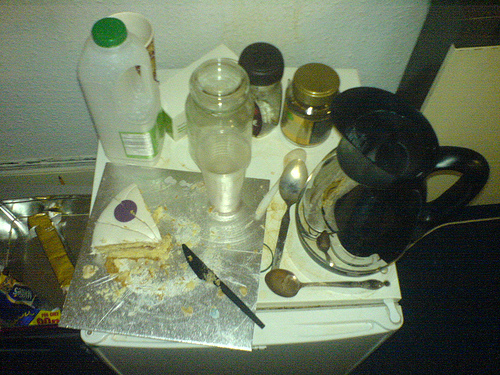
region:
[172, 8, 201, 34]
this is the wall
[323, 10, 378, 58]
the wall is white in color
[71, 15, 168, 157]
this is a bottle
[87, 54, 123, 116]
the bottle is made of plastic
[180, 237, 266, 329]
this is a knife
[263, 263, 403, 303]
this is a spoon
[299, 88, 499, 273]
this is a kettle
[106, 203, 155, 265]
this is a piece of cake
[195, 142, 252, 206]
these are some cups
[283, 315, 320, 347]
the fridge is white in color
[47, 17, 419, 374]
bottles in top of a fridge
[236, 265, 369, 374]
the fridge is white in colour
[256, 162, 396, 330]
spoons are on top of the fridge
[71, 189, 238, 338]
leftovers of a cake on thop of the fridge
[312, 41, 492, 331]
the jug is black in colour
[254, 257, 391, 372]
the fridge is closed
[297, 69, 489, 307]
the jug is shiny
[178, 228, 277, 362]
a knife is on top of the chopping board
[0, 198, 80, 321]
the sink is silver in colour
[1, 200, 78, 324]
paper packs inside the fridge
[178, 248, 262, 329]
this is a knife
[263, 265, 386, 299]
this is a spoon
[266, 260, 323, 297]
the spoon is metallic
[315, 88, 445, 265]
this is a kettle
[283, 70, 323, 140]
this is a container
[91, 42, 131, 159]
this is a bottle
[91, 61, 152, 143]
the bottle is made of plastic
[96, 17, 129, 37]
this is the lid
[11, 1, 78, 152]
this is the wall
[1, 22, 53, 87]
the wall is white in color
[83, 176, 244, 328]
leftover eaten white cake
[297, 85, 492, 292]
silver jug with handle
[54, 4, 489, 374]
serving area on top of mini fridge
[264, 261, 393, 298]
dirty silver spoon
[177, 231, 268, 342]
used black plastic knife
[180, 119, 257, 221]
clear plastic empty cups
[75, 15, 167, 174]
empty plastic container with green top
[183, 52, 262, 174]
clear empty glass jar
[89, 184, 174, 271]
pieces of cake with white frosting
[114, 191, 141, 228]
purple circle decoration on top of cake piece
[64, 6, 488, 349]
items on top of refrigerator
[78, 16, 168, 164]
green cap on jug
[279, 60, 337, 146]
jar with gold lid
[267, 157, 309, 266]
silver spoon with glare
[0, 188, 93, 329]
stainless steel kitchen sink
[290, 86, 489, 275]
coffee server with black handle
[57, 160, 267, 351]
sqaure silver tray with knife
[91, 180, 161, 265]
cake cut in three pieces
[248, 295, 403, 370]
white door of refrigerator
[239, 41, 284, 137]
jar with black cap